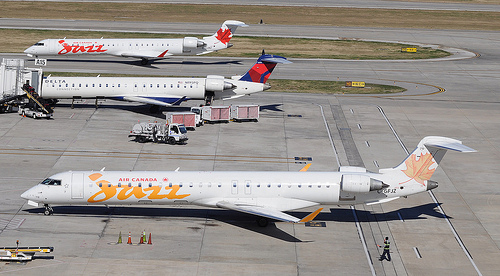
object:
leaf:
[398, 152, 438, 186]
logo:
[87, 172, 191, 203]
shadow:
[24, 199, 456, 245]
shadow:
[47, 96, 286, 121]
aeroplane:
[20, 135, 474, 225]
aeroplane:
[39, 49, 295, 113]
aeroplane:
[23, 19, 251, 58]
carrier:
[162, 104, 260, 130]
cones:
[117, 229, 154, 244]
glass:
[42, 179, 61, 187]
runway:
[1, 47, 500, 92]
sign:
[346, 79, 365, 87]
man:
[378, 236, 392, 260]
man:
[138, 226, 147, 242]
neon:
[116, 227, 154, 245]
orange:
[116, 225, 153, 246]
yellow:
[114, 230, 154, 247]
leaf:
[216, 25, 233, 45]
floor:
[0, 0, 499, 276]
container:
[164, 111, 197, 128]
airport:
[0, 0, 498, 273]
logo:
[58, 40, 108, 55]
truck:
[127, 120, 188, 145]